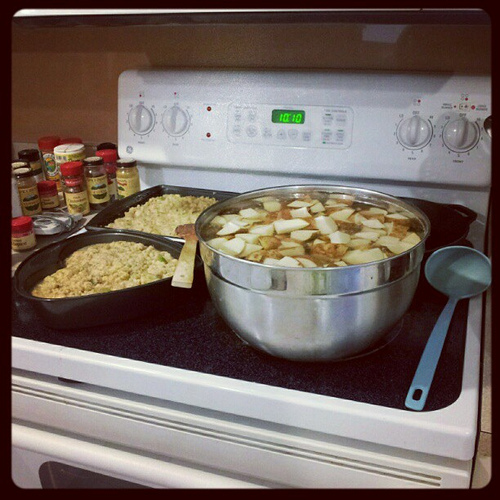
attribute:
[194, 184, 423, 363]
bowl — silver, filled, large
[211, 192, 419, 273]
potatoes — sliced, cut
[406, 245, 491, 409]
spoon — blue, wooden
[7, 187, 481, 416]
stove — grainy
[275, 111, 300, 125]
letters — green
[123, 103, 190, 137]
knobs — white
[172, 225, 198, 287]
spoon — wooden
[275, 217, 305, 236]
potato — cut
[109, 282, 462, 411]
surface — black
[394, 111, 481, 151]
knobs — white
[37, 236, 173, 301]
casserole — tan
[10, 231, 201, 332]
dish — heart-shaped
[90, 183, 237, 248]
pan — square